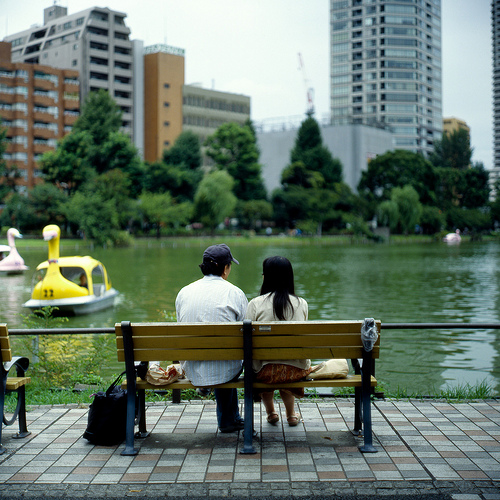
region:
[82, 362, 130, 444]
a black bag on ground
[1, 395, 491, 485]
a tiled sidewalk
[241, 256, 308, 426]
a lady sitting on bench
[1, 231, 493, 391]
the greenish water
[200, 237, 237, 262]
a blue cap on man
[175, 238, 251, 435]
a man sitting on bench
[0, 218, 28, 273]
a pink swan boat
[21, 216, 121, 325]
blue and yellow boat with duck head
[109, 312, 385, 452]
metal framed wood park bench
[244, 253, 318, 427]
woman with long black hair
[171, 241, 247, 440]
man wearing black baseball cap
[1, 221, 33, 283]
pink and white duck boat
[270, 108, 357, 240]
dark green pine tree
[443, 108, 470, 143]
yellow building behind white building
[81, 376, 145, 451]
bag on ground next to man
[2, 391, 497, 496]
multi colored brick deck next to lake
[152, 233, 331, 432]
Two people sitting on a park bench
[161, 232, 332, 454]
A man and a woman sitting on a park bench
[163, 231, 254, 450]
A man wearing a baseball hat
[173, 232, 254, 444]
a man wearing a baseball hat sitting on a bench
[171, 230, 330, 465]
a lady sitting next to a man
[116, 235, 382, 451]
Two people on a bench watching the water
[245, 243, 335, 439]
a lady with long hair watching the water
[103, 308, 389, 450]
metal framed wood park bench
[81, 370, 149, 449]
black bag on ground next to man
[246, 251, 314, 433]
woman with long black hair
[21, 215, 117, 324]
blue and yellow duck boat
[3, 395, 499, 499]
small brick sitting deck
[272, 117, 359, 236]
large green pine tree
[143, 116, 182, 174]
orange building with two windows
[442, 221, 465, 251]
white duck boat in distance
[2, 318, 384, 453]
the wooden benches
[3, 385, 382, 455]
the legs of benches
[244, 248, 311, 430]
a lady sitting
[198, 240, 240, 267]
a blue hat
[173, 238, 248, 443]
a man sitting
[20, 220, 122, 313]
a yellow boat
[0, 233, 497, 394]
the greenish water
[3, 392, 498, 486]
the tiled sidewalk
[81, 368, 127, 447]
a black bag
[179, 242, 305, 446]
2 people on a bench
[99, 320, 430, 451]
a wooden and metal bench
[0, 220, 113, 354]
boats shaped like ducks